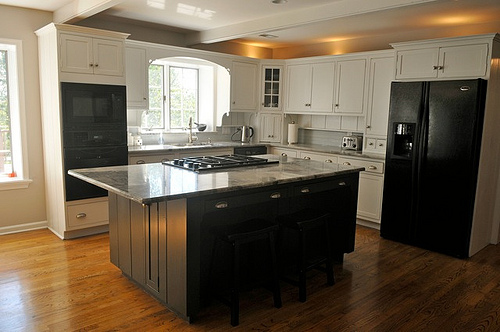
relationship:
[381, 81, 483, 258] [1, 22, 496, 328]
refrigerator in kitchen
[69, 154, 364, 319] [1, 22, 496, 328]
island in kitchen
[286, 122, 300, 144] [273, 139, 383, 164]
paper towels on counter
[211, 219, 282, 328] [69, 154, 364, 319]
stool at island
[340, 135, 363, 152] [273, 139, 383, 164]
toaster on counter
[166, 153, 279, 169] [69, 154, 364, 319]
stove burner on island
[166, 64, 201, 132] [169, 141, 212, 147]
window above sink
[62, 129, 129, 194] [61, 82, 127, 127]
oven under microwave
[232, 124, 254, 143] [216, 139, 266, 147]
coffee maker on counter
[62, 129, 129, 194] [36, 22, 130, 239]
oven in wall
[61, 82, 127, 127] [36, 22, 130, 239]
microwave in wall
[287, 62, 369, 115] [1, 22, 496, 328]
cabinets in kitchen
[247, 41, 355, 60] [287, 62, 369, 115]
light above cabinets